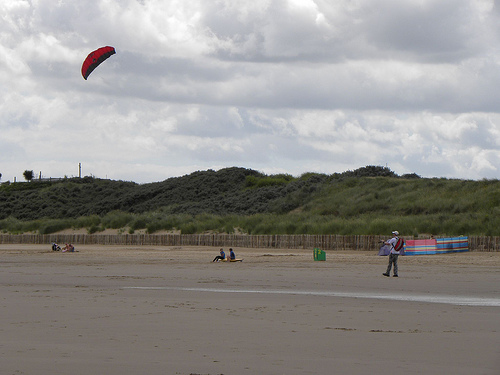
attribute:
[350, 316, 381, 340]
mark — black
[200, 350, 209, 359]
mark — black, spotted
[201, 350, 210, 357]
mark — spotted, black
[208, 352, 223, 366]
mark — black, spotted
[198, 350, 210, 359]
mark — spotted, black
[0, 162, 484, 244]
hill — green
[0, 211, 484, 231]
greenery — lush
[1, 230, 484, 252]
fence — long, wooden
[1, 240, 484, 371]
beach — sandy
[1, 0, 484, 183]
sky — cloudy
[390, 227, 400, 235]
cap — baseball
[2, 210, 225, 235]
grass — tall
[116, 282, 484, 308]
patch — wet, sand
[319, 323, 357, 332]
mark — black, spotted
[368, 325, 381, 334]
mark — spotted, black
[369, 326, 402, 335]
mark — black, spotted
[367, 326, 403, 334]
mark — spotted, black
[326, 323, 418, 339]
spotted — black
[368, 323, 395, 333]
mark — black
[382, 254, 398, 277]
pants — gray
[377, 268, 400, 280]
shoes — black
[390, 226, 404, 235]
hat — gray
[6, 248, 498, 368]
beach — brown, sandy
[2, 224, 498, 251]
fence — wooden